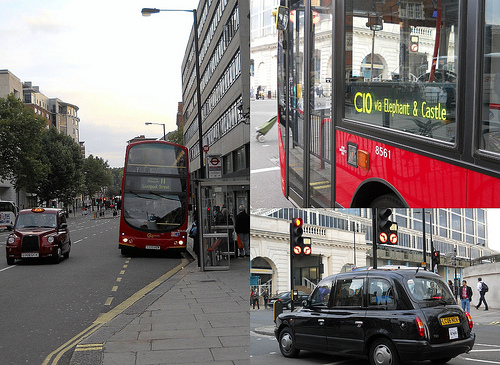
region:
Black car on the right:
[270, 258, 493, 362]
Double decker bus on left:
[106, 117, 203, 259]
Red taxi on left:
[6, 204, 78, 274]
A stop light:
[285, 216, 322, 262]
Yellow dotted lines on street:
[83, 259, 140, 321]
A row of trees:
[7, 94, 104, 201]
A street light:
[138, 4, 239, 264]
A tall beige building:
[174, 17, 249, 155]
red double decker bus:
[115, 136, 193, 256]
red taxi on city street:
[10, 205, 70, 260]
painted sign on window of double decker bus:
[347, 84, 452, 132]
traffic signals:
[371, 211, 398, 246]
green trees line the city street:
[4, 107, 106, 221]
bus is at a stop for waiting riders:
[120, 140, 242, 272]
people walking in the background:
[455, 273, 493, 311]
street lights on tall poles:
[136, 1, 207, 142]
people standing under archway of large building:
[247, 253, 278, 309]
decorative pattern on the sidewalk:
[157, 290, 239, 357]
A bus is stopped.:
[117, 139, 188, 258]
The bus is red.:
[135, 234, 170, 246]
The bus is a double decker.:
[116, 139, 189, 251]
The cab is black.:
[273, 268, 474, 364]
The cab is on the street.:
[273, 267, 473, 364]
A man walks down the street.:
[473, 275, 492, 310]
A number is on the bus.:
[374, 145, 391, 160]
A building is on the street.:
[203, 0, 248, 150]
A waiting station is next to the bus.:
[192, 180, 247, 270]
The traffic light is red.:
[291, 217, 304, 229]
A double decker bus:
[116, 139, 194, 258]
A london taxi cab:
[271, 272, 479, 364]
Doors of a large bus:
[284, 0, 334, 205]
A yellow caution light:
[291, 214, 304, 248]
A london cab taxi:
[6, 203, 75, 265]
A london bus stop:
[196, 177, 248, 267]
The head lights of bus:
[117, 235, 183, 249]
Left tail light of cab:
[411, 314, 431, 341]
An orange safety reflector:
[353, 150, 369, 169]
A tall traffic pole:
[139, 7, 208, 259]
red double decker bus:
[95, 125, 187, 270]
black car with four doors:
[270, 248, 486, 355]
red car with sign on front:
[5, 196, 75, 265]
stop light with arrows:
[280, 205, 316, 270]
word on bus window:
[347, 85, 447, 125]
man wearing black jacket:
[457, 278, 473, 315]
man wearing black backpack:
[472, 272, 492, 314]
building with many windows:
[145, 3, 246, 151]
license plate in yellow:
[439, 306, 464, 330]